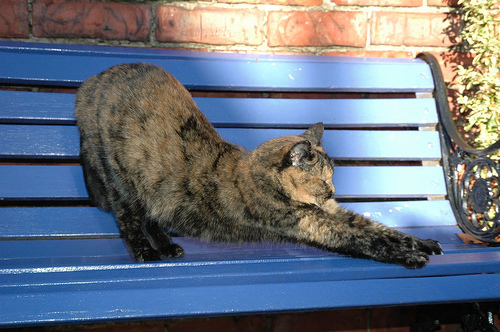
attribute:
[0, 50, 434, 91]
panel — wooden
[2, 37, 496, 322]
bench — blue  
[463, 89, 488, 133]
leaves — green 